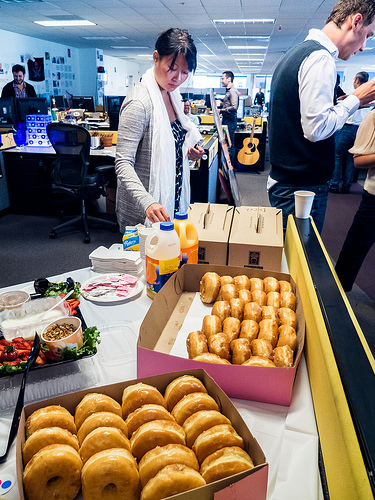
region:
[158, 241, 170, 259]
Part of the bottle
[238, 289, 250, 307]
Part of the doughnuts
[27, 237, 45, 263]
Part of the floor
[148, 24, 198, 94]
The head of the person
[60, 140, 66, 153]
Part of the chair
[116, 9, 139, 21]
Part of the ceiling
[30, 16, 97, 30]
A light on the ceiling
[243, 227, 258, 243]
Part of the cardboard box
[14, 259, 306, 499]
two boxes full doughnuts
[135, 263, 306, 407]
doughnut box is pink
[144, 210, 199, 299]
two bottles of orange juice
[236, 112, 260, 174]
guitar is next to desk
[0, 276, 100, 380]
black tray has food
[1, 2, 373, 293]
people inside an office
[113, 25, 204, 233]
woman with black hair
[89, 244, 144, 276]
napkins next to orange juice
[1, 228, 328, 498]
table has white tablecloth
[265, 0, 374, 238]
man wearing dark vest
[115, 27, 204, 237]
A black haired Asian woman in a grey sweater.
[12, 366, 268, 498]
A pink cardboard container with 17 glazed donuts inside.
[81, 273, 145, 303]
A white plate on a table with white and pink sugar packets on it.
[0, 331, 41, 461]
A long black right side of tongs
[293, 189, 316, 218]
White cup on a black rail.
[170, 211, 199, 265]
A full jug of orange juice with a blue lid.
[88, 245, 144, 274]
A rectangle stack of white napkins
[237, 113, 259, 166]
A long brown acoustic guitar.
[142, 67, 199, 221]
Long white scarf around a woman's neck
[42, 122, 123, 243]
A black and silver desk chair behind a woman looking at juice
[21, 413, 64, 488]
Golden brown doughnuts in a box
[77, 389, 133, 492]
Golden brown doughnuts in a box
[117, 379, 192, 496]
Golden brown doughnuts in a box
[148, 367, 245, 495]
Golden brown doughnuts in a box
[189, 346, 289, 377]
Golden brown doughnuts in a box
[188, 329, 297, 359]
Golden brown doughnuts in a box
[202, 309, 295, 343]
Golden brown doughnuts in a box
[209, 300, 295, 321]
Golden brown doughnuts in a box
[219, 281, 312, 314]
Golden brown doughnuts in a box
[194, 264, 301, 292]
Golden brown doughnuts in a box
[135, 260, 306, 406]
Pink box with glazed donuts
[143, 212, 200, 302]
Two containers of orange juice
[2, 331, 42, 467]
Large black plastic spoon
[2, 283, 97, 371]
Black tray with strawberries and other food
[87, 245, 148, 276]
Stack of white napkins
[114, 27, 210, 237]
Dark haired woman wearing white scarf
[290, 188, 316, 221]
Small white disposable cup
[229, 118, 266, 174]
Guitar leaning against desk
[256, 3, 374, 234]
Man wearing a black vest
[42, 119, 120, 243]
Black swivel office chair